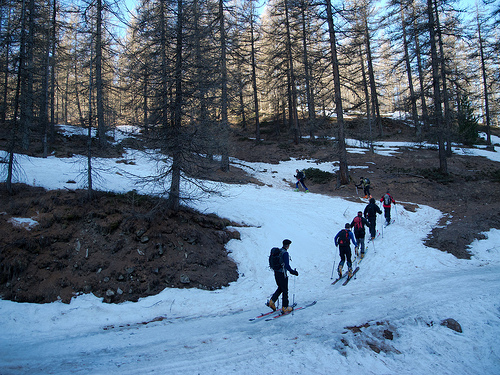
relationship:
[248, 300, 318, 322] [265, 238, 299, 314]
ski under person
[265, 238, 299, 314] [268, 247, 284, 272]
person has backpack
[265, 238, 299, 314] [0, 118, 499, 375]
person walking up hill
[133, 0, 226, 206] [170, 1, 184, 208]
tree has stem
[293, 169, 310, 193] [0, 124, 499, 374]
person in snow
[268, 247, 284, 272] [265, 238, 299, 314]
backpack on person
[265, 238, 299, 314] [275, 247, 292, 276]
person has coat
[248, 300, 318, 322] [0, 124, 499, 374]
ski on snow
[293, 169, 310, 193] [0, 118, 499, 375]
person on hil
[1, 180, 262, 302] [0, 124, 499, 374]
dirt in snow